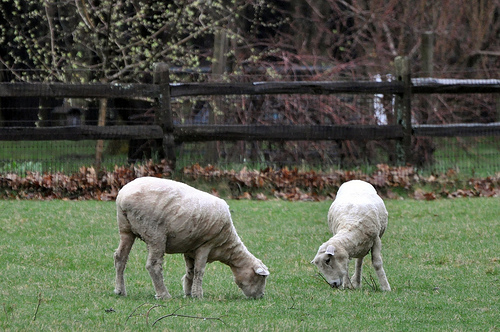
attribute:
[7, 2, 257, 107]
leaves — green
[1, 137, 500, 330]
grass — green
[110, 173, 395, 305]
sheep — white, grazing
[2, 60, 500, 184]
fence — brown, wooden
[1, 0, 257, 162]
tree — bare